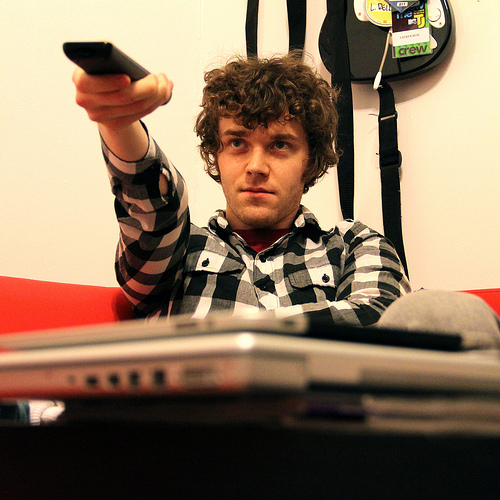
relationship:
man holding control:
[101, 49, 413, 327] [63, 43, 174, 107]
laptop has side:
[3, 309, 495, 401] [3, 332, 247, 394]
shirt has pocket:
[100, 125, 413, 332] [167, 255, 246, 315]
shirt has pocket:
[100, 125, 413, 332] [286, 262, 343, 305]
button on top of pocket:
[203, 259, 210, 267] [167, 255, 246, 315]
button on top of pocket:
[323, 272, 331, 284] [286, 262, 343, 305]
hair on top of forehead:
[195, 48, 343, 195] [220, 108, 300, 130]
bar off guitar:
[372, 26, 393, 91] [318, 3, 453, 83]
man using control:
[101, 49, 413, 327] [63, 43, 174, 107]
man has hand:
[101, 49, 413, 327] [74, 67, 174, 120]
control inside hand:
[63, 43, 174, 107] [74, 67, 174, 120]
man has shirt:
[101, 49, 413, 327] [100, 125, 413, 332]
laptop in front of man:
[3, 309, 495, 401] [101, 49, 413, 327]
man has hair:
[101, 49, 413, 327] [195, 48, 343, 195]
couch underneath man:
[2, 276, 497, 333] [101, 49, 413, 327]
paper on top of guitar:
[394, 44, 432, 58] [318, 3, 453, 83]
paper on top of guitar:
[392, 27, 430, 46] [318, 3, 453, 83]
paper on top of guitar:
[394, 4, 428, 31] [318, 3, 453, 83]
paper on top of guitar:
[364, 3, 391, 28] [318, 3, 453, 83]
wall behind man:
[5, 3, 495, 290] [101, 49, 413, 327]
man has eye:
[101, 49, 413, 327] [227, 138, 246, 151]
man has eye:
[101, 49, 413, 327] [271, 140, 289, 153]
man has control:
[101, 49, 413, 327] [63, 43, 174, 107]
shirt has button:
[100, 125, 413, 332] [203, 259, 210, 267]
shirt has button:
[100, 125, 413, 332] [323, 272, 331, 284]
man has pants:
[101, 49, 413, 327] [374, 290, 497, 351]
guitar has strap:
[318, 3, 453, 83] [318, 4, 356, 220]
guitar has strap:
[318, 3, 453, 83] [377, 80, 410, 285]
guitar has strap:
[318, 3, 453, 83] [245, 3, 259, 61]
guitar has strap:
[318, 3, 453, 83] [288, 3, 308, 59]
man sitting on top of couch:
[101, 49, 413, 327] [2, 276, 497, 333]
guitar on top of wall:
[318, 3, 453, 83] [5, 3, 495, 290]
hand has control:
[74, 67, 174, 120] [63, 43, 174, 107]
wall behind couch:
[5, 3, 495, 290] [2, 276, 497, 333]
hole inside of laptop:
[87, 374, 101, 388] [3, 309, 495, 401]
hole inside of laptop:
[109, 374, 120, 389] [3, 309, 495, 401]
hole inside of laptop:
[130, 372, 140, 388] [3, 309, 495, 401]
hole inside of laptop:
[154, 371, 166, 385] [3, 309, 495, 401]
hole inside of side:
[87, 374, 101, 388] [3, 332, 247, 394]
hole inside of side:
[109, 374, 120, 389] [3, 332, 247, 394]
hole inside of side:
[130, 372, 140, 388] [3, 332, 247, 394]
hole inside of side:
[154, 371, 166, 385] [3, 332, 247, 394]